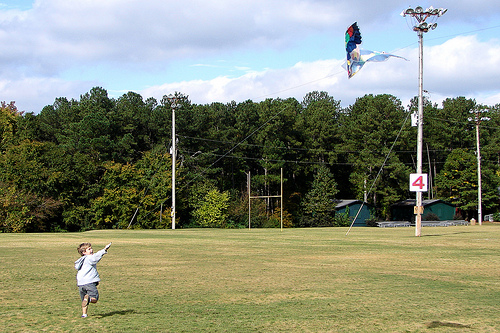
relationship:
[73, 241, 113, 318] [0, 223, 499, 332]
boy in field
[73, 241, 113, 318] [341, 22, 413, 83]
boy flying a kite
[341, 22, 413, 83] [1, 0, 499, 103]
kite in sky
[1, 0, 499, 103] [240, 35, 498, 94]
sky has clouds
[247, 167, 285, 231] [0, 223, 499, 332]
goal post in field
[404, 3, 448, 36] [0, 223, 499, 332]
lights are above field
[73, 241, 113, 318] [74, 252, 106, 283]
boy wearing a hoodie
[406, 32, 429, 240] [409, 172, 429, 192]
pole has a sign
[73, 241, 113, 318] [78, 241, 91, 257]
boy has hair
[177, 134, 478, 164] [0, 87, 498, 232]
wires in front of trees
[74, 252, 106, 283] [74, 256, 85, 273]
sweatshirt has a hood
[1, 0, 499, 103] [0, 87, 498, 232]
sky above trees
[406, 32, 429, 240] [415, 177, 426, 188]
pole has a number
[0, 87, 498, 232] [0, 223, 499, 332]
trees are at end of th field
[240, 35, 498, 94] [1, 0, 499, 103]
clouds are in sky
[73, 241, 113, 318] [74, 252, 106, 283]
boy has a jacket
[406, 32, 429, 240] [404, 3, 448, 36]
pole has lights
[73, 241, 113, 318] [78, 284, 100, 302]
boy wearing shorts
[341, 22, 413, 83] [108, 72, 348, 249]
kite has a string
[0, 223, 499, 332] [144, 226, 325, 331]
field of grass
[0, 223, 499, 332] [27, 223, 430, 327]
grass on field